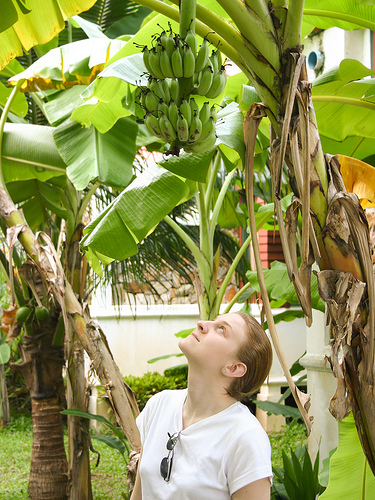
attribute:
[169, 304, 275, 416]
head of a person — pictured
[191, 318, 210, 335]
nose of a person — pictured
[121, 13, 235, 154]
unripe green bananas — unripe,green and bunch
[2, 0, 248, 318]
thin green leaves — tall,thin and green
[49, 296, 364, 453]
tall white fence — tall and white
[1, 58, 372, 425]
brown dead leaves — brown and dead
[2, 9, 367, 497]
banana trees — multiple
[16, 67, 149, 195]
large green leaf — large and green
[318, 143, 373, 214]
one yellow leaf — dried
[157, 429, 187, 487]
pair of sunglasses — black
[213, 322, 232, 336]
left eye of a person — looking up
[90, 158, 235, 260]
leaf — large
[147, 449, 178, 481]
sunglasses — black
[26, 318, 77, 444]
banana tree — green and brown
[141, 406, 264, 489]
t-shirt — white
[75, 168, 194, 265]
leaves — large and green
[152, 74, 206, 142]
bananas — bunch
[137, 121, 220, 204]
bananas — green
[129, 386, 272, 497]
t-shirt — white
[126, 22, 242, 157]
bananas — unripe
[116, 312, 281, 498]
person — looking up